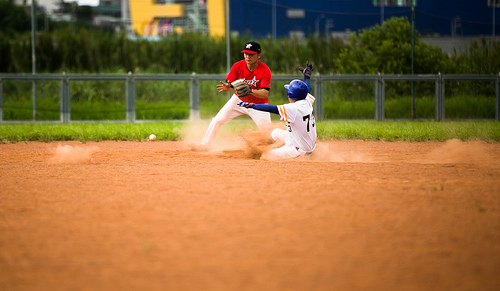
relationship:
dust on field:
[144, 103, 314, 169] [209, 106, 445, 261]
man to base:
[236, 61, 319, 159] [201, 116, 253, 165]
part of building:
[198, 6, 224, 32] [158, 12, 223, 30]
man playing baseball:
[236, 61, 319, 159] [121, 25, 357, 185]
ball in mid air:
[147, 135, 156, 142] [110, 51, 235, 159]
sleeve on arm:
[261, 85, 270, 92] [234, 88, 287, 123]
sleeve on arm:
[224, 82, 291, 130] [300, 70, 324, 103]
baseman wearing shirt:
[196, 36, 282, 160] [217, 55, 276, 103]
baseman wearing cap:
[196, 36, 282, 160] [235, 39, 262, 63]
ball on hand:
[147, 135, 156, 142] [214, 74, 248, 99]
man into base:
[236, 61, 319, 159] [187, 112, 287, 181]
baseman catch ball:
[196, 36, 282, 160] [130, 116, 163, 149]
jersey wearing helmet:
[226, 60, 267, 100] [284, 75, 315, 108]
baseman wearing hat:
[196, 36, 282, 160] [236, 32, 261, 61]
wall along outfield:
[62, 50, 424, 164] [58, 29, 439, 283]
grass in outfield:
[390, 112, 454, 144] [47, 36, 438, 229]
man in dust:
[236, 61, 319, 159] [140, 120, 238, 161]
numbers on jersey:
[287, 112, 337, 142] [256, 93, 316, 169]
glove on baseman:
[216, 79, 253, 106] [188, 30, 297, 154]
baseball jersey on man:
[275, 94, 317, 149] [241, 77, 392, 177]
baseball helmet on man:
[284, 79, 307, 97] [251, 77, 335, 212]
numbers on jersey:
[297, 114, 315, 135] [265, 90, 335, 167]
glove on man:
[286, 54, 311, 68] [225, 73, 344, 210]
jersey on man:
[214, 51, 267, 100] [202, 41, 302, 149]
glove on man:
[231, 79, 253, 98] [203, 35, 298, 139]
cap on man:
[235, 39, 262, 63] [194, 39, 344, 190]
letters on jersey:
[233, 80, 264, 109] [218, 55, 267, 104]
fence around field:
[94, 52, 494, 136] [58, 90, 477, 189]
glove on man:
[231, 79, 253, 98] [192, 54, 298, 141]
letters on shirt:
[248, 80, 262, 90] [219, 47, 302, 115]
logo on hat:
[240, 40, 265, 53] [233, 36, 284, 73]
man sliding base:
[236, 61, 319, 159] [191, 127, 270, 170]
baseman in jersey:
[196, 36, 282, 160] [217, 55, 277, 108]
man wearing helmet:
[236, 61, 319, 159] [282, 75, 303, 94]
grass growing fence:
[342, 115, 458, 148] [16, 60, 481, 127]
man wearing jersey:
[236, 61, 319, 159] [261, 94, 328, 144]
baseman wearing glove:
[196, 36, 282, 160] [226, 68, 250, 98]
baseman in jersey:
[196, 36, 282, 160] [226, 60, 267, 100]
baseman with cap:
[196, 36, 282, 160] [242, 36, 262, 57]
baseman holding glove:
[196, 36, 282, 160] [226, 67, 253, 100]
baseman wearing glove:
[196, 36, 282, 160] [216, 75, 257, 94]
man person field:
[236, 61, 319, 159] [2, 131, 484, 264]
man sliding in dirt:
[236, 61, 319, 159] [0, 139, 497, 287]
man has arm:
[236, 61, 319, 159] [236, 61, 317, 120]